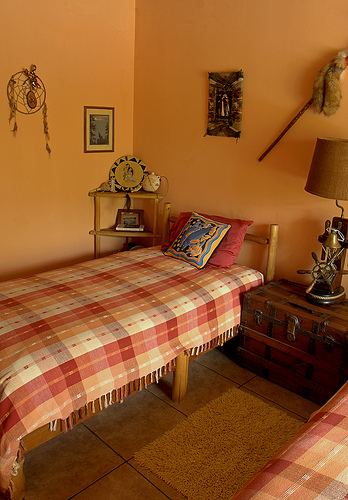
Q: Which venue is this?
A: This is a bedroom.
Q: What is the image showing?
A: It is showing a bedroom.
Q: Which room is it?
A: It is a bedroom.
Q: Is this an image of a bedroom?
A: Yes, it is showing a bedroom.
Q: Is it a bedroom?
A: Yes, it is a bedroom.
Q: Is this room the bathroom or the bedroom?
A: It is the bedroom.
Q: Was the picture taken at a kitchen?
A: No, the picture was taken in a bedroom.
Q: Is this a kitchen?
A: No, it is a bedroom.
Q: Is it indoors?
A: Yes, it is indoors.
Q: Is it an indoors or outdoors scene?
A: It is indoors.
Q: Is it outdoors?
A: No, it is indoors.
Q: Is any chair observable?
A: No, there are no chairs.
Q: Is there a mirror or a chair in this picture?
A: No, there are no chairs or mirrors.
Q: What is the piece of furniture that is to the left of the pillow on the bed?
A: The piece of furniture is a shelf.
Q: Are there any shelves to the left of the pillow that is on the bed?
A: Yes, there is a shelf to the left of the pillow.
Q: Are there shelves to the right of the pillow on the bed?
A: No, the shelf is to the left of the pillow.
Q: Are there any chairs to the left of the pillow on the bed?
A: No, there is a shelf to the left of the pillow.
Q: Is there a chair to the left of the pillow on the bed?
A: No, there is a shelf to the left of the pillow.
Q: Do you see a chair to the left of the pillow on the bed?
A: No, there is a shelf to the left of the pillow.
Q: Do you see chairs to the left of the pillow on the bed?
A: No, there is a shelf to the left of the pillow.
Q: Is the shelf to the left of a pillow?
A: Yes, the shelf is to the left of a pillow.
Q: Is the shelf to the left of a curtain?
A: No, the shelf is to the left of a pillow.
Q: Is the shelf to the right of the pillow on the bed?
A: No, the shelf is to the left of the pillow.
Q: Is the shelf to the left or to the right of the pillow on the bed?
A: The shelf is to the left of the pillow.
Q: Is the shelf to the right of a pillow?
A: No, the shelf is to the left of a pillow.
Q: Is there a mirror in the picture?
A: No, there are no mirrors.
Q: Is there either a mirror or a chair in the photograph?
A: No, there are no mirrors or chairs.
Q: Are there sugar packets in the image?
A: No, there are no sugar packets.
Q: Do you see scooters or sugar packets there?
A: No, there are no sugar packets or scooters.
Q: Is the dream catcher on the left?
A: Yes, the dream catcher is on the left of the image.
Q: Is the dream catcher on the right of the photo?
A: No, the dream catcher is on the left of the image.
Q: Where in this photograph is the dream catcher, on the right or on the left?
A: The dream catcher is on the left of the image.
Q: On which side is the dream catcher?
A: The dream catcher is on the left of the image.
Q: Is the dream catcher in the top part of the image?
A: Yes, the dream catcher is in the top of the image.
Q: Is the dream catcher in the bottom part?
A: No, the dream catcher is in the top of the image.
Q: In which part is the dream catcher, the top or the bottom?
A: The dream catcher is in the top of the image.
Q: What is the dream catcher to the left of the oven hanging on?
A: The dream catcher is hanging on the wall.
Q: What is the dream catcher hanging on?
A: The dream catcher is hanging on the wall.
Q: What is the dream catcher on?
A: The dream catcher is on the wall.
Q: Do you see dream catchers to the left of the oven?
A: Yes, there is a dream catcher to the left of the oven.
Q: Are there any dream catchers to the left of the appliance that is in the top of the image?
A: Yes, there is a dream catcher to the left of the oven.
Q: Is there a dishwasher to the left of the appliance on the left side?
A: No, there is a dream catcher to the left of the oven.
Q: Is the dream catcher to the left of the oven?
A: Yes, the dream catcher is to the left of the oven.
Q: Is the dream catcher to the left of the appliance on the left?
A: Yes, the dream catcher is to the left of the oven.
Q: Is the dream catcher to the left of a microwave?
A: No, the dream catcher is to the left of the oven.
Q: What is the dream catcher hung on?
A: The dream catcher is hung on the wall.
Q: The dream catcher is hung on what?
A: The dream catcher is hung on the wall.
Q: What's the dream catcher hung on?
A: The dream catcher is hung on the wall.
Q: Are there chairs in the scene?
A: No, there are no chairs.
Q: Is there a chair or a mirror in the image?
A: No, there are no chairs or mirrors.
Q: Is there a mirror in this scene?
A: No, there are no mirrors.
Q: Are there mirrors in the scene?
A: No, there are no mirrors.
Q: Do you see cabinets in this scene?
A: Yes, there is a cabinet.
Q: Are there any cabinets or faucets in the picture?
A: Yes, there is a cabinet.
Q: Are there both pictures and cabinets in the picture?
A: Yes, there are both a cabinet and a picture.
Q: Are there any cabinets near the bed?
A: Yes, there is a cabinet near the bed.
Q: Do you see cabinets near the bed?
A: Yes, there is a cabinet near the bed.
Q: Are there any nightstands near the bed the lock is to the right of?
A: No, there is a cabinet near the bed.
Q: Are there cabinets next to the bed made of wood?
A: Yes, there is a cabinet next to the bed.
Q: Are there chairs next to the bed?
A: No, there is a cabinet next to the bed.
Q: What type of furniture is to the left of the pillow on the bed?
A: The piece of furniture is a cabinet.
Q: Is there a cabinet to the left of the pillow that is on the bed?
A: Yes, there is a cabinet to the left of the pillow.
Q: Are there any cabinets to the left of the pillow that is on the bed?
A: Yes, there is a cabinet to the left of the pillow.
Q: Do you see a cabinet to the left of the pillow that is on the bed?
A: Yes, there is a cabinet to the left of the pillow.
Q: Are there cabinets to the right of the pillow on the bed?
A: No, the cabinet is to the left of the pillow.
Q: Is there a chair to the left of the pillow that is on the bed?
A: No, there is a cabinet to the left of the pillow.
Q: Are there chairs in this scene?
A: No, there are no chairs.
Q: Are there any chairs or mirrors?
A: No, there are no chairs or mirrors.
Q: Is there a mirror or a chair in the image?
A: No, there are no mirrors or chairs.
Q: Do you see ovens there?
A: Yes, there is an oven.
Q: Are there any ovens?
A: Yes, there is an oven.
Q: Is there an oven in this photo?
A: Yes, there is an oven.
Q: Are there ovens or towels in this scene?
A: Yes, there is an oven.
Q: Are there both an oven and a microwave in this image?
A: No, there is an oven but no microwaves.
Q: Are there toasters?
A: No, there are no toasters.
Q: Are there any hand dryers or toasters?
A: No, there are no toasters or hand dryers.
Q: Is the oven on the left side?
A: Yes, the oven is on the left of the image.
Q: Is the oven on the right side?
A: No, the oven is on the left of the image.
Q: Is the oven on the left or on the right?
A: The oven is on the left of the image.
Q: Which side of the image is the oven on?
A: The oven is on the left of the image.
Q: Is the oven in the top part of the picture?
A: Yes, the oven is in the top of the image.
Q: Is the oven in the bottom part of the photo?
A: No, the oven is in the top of the image.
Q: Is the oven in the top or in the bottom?
A: The oven is in the top of the image.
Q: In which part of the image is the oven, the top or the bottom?
A: The oven is in the top of the image.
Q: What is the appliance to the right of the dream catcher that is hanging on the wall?
A: The appliance is an oven.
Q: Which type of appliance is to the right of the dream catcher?
A: The appliance is an oven.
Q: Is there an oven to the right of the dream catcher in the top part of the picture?
A: Yes, there is an oven to the right of the dream catcher.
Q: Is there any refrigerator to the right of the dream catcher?
A: No, there is an oven to the right of the dream catcher.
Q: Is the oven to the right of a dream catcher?
A: Yes, the oven is to the right of a dream catcher.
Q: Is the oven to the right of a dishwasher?
A: No, the oven is to the right of a dream catcher.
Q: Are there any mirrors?
A: No, there are no mirrors.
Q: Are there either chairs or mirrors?
A: No, there are no mirrors or chairs.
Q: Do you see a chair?
A: No, there are no chairs.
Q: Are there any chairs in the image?
A: No, there are no chairs.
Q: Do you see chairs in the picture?
A: No, there are no chairs.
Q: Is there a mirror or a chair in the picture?
A: No, there are no chairs or mirrors.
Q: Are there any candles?
A: No, there are no candles.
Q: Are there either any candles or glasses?
A: No, there are no candles or glasses.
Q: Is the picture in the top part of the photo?
A: Yes, the picture is in the top of the image.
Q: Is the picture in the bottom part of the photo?
A: No, the picture is in the top of the image.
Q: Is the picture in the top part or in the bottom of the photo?
A: The picture is in the top of the image.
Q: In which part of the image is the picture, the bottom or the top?
A: The picture is in the top of the image.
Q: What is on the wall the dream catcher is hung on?
A: The picture is on the wall.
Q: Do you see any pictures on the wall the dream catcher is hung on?
A: Yes, there is a picture on the wall.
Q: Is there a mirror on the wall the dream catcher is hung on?
A: No, there is a picture on the wall.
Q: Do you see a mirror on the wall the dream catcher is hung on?
A: No, there is a picture on the wall.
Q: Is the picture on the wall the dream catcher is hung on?
A: Yes, the picture is on the wall.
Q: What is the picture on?
A: The picture is on the wall.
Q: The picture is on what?
A: The picture is on the wall.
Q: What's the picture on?
A: The picture is on the wall.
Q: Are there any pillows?
A: Yes, there is a pillow.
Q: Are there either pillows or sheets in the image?
A: Yes, there is a pillow.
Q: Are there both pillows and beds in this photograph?
A: Yes, there are both a pillow and a bed.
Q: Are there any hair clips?
A: No, there are no hair clips.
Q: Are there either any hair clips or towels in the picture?
A: No, there are no hair clips or towels.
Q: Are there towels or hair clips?
A: No, there are no hair clips or towels.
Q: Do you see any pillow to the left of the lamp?
A: Yes, there is a pillow to the left of the lamp.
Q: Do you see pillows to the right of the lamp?
A: No, the pillow is to the left of the lamp.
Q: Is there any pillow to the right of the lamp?
A: No, the pillow is to the left of the lamp.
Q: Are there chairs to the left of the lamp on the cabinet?
A: No, there is a pillow to the left of the lamp.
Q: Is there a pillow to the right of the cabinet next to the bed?
A: Yes, there is a pillow to the right of the cabinet.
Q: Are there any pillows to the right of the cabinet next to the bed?
A: Yes, there is a pillow to the right of the cabinet.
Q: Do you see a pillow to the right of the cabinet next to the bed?
A: Yes, there is a pillow to the right of the cabinet.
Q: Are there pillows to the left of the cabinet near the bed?
A: No, the pillow is to the right of the cabinet.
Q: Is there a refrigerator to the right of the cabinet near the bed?
A: No, there is a pillow to the right of the cabinet.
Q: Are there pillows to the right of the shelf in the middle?
A: Yes, there is a pillow to the right of the shelf.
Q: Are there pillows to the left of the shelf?
A: No, the pillow is to the right of the shelf.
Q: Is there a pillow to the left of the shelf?
A: No, the pillow is to the right of the shelf.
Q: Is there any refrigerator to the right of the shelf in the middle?
A: No, there is a pillow to the right of the shelf.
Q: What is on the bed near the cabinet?
A: The pillow is on the bed.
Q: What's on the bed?
A: The pillow is on the bed.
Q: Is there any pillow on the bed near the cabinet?
A: Yes, there is a pillow on the bed.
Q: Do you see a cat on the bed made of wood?
A: No, there is a pillow on the bed.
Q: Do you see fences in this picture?
A: No, there are no fences.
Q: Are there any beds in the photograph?
A: Yes, there is a bed.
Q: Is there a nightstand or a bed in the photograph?
A: Yes, there is a bed.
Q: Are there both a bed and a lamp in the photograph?
A: Yes, there are both a bed and a lamp.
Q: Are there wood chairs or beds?
A: Yes, there is a wood bed.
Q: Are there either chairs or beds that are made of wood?
A: Yes, the bed is made of wood.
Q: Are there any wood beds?
A: Yes, there is a wood bed.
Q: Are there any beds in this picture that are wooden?
A: Yes, there is a bed that is wooden.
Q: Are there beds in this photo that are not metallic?
A: Yes, there is a wooden bed.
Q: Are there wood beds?
A: Yes, there is a bed that is made of wood.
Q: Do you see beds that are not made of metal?
A: Yes, there is a bed that is made of wood.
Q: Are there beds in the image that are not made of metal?
A: Yes, there is a bed that is made of wood.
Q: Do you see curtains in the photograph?
A: No, there are no curtains.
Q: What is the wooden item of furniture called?
A: The piece of furniture is a bed.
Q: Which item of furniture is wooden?
A: The piece of furniture is a bed.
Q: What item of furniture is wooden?
A: The piece of furniture is a bed.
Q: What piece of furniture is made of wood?
A: The piece of furniture is a bed.